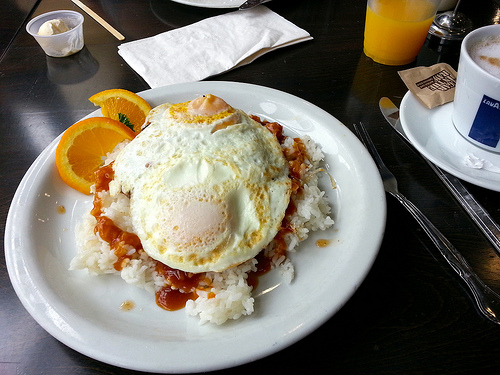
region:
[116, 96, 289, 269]
the egg is fried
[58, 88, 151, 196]
the oranges are cut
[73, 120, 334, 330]
the rice is cooked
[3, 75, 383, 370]
the plate is white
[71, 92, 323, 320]
the rice has ketchup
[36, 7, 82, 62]
the cup has butter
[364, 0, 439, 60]
the cup has orange juice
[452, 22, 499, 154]
the mug is blue and white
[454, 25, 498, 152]
the mug has coffee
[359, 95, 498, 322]
the silverware is on the table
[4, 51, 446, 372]
a plate of food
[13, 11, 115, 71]
a plastic cup of butter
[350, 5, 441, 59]
a cup of orange juice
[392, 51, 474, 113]
sugar in the raw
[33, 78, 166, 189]
two orange slices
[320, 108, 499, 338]
a silver fork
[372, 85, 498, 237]
a silver butter knife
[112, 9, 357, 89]
a paper napkin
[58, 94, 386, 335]
eggs on top of rice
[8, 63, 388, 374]
food on a round white plate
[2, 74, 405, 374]
food on a plate.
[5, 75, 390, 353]
the plate is white.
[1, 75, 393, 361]
the plate is round.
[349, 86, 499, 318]
the utensils are silver.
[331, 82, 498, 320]
knife and fork on the table.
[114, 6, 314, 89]
the napkin is white.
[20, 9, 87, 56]
butter in a cup.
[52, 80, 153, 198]
the oranges are orange.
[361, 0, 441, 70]
the drink is orange.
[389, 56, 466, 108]
sugar packet is brown.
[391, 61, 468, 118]
Brown package of sugar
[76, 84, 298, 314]
eggs on rice with sauce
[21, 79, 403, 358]
round white plate with food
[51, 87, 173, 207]
oranges used as a garnish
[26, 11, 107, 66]
small cup of butter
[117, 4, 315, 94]
white napkin on table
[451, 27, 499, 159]
white and blue cup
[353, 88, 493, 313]
fork and knife on table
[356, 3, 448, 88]
cup of orange juice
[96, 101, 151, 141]
green sprig by oranges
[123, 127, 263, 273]
Sunny side up eggs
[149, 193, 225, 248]
Yolk of sunny side up egg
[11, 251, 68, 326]
White plate on table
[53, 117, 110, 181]
Orange slices on white plate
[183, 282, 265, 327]
White rice on white plate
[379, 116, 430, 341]
Silver fork on table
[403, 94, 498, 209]
Small white saucer on table.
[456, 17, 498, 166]
Cup of coffee on saucer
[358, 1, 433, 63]
Half cup of orange juice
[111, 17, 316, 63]
White napkin on table